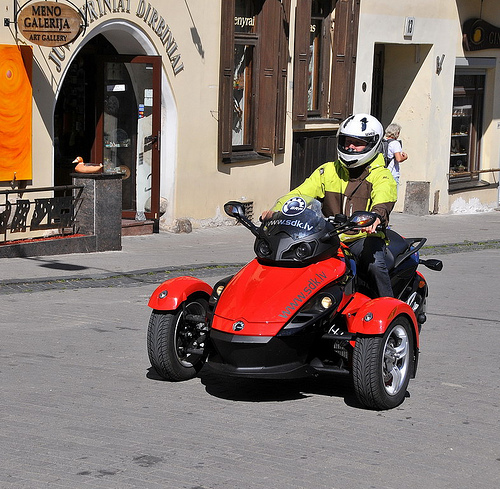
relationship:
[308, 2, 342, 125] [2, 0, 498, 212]
window on building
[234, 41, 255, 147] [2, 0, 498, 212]
window on building